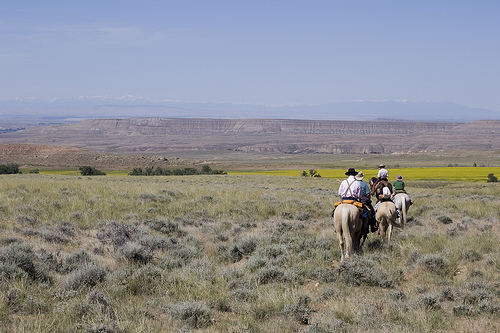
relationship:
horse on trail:
[375, 202, 395, 251] [251, 146, 458, 177]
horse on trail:
[333, 203, 370, 261] [269, 145, 477, 172]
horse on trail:
[333, 203, 370, 261] [274, 140, 477, 175]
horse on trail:
[328, 198, 365, 260] [2, 173, 497, 331]